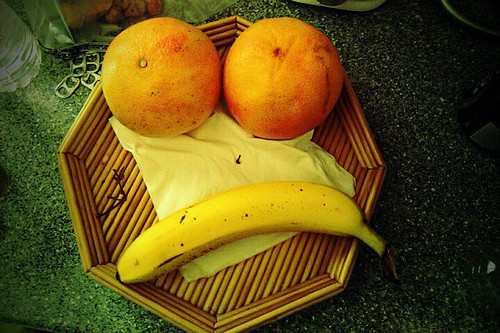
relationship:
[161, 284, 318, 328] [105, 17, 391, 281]
plate has fruit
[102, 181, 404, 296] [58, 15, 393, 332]
banana sitting in basket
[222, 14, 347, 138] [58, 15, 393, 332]
orange on side of basket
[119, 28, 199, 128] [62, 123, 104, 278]
orange on left side of basket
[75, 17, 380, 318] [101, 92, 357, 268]
basket holding napkin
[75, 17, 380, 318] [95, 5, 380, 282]
basket holding fruit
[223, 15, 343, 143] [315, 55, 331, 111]
grapefruit with a bruise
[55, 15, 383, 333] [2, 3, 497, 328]
plate sitting on counter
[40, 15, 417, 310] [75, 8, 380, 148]
basket of fruit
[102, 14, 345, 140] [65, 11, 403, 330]
fruit arranged to make a frowning face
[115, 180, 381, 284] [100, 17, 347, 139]
banana with orange